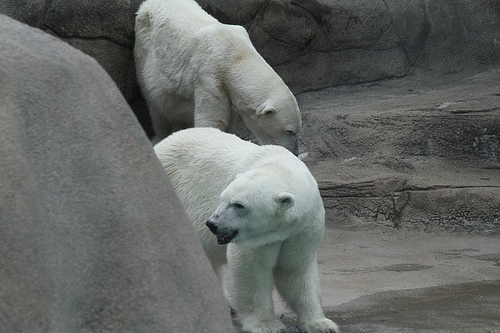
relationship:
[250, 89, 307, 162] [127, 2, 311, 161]
head of polar bear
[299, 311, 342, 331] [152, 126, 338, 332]
foot of bear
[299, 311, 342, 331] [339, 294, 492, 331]
foot in water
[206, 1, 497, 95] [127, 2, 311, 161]
rock by polar bear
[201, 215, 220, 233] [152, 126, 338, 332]
nose of bear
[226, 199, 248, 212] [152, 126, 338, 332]
eye of bear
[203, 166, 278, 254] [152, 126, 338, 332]
head of bear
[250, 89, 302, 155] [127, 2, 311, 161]
head of polar bear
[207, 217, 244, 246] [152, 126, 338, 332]
mouth of bear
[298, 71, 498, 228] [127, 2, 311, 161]
steps near polar bear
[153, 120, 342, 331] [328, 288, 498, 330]
bear's paw in water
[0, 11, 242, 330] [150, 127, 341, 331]
rock next to bear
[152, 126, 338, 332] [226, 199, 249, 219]
bear has eye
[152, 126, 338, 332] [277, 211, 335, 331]
bear has leg